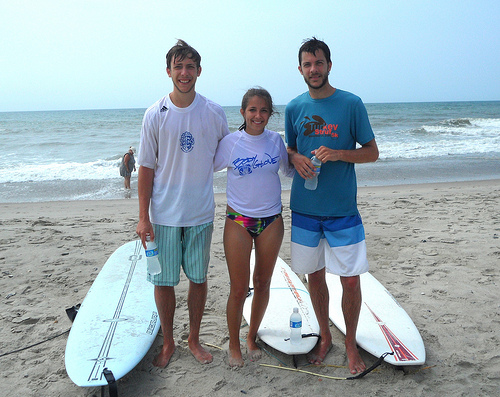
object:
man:
[283, 36, 379, 375]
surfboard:
[303, 237, 427, 367]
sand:
[2, 198, 497, 395]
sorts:
[286, 211, 369, 277]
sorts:
[139, 207, 211, 289]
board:
[62, 237, 162, 389]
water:
[26, 56, 448, 206]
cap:
[291, 306, 301, 315]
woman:
[210, 82, 295, 368]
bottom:
[222, 207, 282, 237]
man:
[134, 37, 230, 368]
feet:
[153, 343, 176, 372]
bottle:
[303, 151, 325, 193]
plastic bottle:
[141, 234, 162, 275]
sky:
[0, 0, 498, 105]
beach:
[0, 175, 497, 395]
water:
[287, 302, 301, 349]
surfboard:
[232, 247, 321, 355]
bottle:
[288, 303, 300, 339]